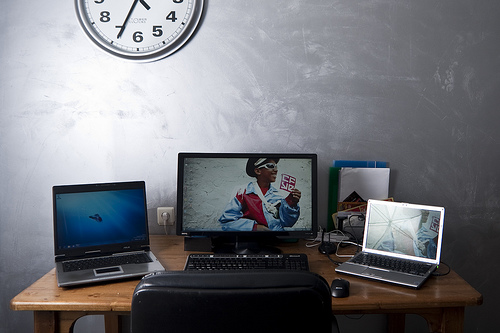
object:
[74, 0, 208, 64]
clock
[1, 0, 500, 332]
wall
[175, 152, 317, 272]
computer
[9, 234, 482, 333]
desk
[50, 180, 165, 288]
laptop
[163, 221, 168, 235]
power cord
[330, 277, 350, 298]
mouse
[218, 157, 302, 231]
man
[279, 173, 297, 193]
sign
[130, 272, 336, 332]
chair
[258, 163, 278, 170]
sunglasses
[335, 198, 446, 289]
laptop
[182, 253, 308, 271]
keyboard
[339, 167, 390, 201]
papers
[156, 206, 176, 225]
electric socket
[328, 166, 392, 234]
file